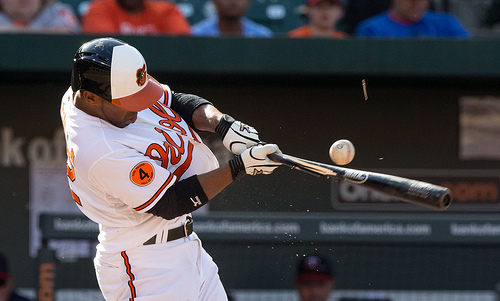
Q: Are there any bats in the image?
A: Yes, there is a bat.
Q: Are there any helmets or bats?
A: Yes, there is a bat.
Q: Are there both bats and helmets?
A: Yes, there are both a bat and a helmet.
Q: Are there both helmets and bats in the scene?
A: Yes, there are both a bat and a helmet.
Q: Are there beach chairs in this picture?
A: No, there are no beach chairs.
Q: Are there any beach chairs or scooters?
A: No, there are no beach chairs or scooters.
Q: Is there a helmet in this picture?
A: Yes, there is a helmet.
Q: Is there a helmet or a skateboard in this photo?
A: Yes, there is a helmet.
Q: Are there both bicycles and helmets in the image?
A: No, there is a helmet but no bicycles.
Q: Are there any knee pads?
A: No, there are no knee pads.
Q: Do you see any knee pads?
A: No, there are no knee pads.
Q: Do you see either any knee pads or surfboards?
A: No, there are no knee pads or surfboards.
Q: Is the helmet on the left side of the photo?
A: Yes, the helmet is on the left of the image.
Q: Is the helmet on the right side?
A: No, the helmet is on the left of the image.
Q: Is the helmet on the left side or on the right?
A: The helmet is on the left of the image.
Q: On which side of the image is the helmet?
A: The helmet is on the left of the image.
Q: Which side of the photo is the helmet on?
A: The helmet is on the left of the image.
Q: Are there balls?
A: Yes, there is a ball.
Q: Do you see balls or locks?
A: Yes, there is a ball.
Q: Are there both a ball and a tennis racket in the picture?
A: No, there is a ball but no rackets.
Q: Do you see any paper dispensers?
A: No, there are no paper dispensers.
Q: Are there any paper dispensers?
A: No, there are no paper dispensers.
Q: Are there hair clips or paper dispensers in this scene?
A: No, there are no paper dispensers or hair clips.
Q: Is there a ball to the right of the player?
A: Yes, there is a ball to the right of the player.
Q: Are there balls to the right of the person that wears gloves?
A: Yes, there is a ball to the right of the player.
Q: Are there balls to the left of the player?
A: No, the ball is to the right of the player.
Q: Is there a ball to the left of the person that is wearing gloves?
A: No, the ball is to the right of the player.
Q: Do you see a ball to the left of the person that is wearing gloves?
A: No, the ball is to the right of the player.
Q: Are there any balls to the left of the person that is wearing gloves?
A: No, the ball is to the right of the player.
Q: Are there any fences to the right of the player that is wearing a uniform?
A: No, there is a ball to the right of the player.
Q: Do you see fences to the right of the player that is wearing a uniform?
A: No, there is a ball to the right of the player.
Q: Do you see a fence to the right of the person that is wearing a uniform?
A: No, there is a ball to the right of the player.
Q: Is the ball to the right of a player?
A: Yes, the ball is to the right of a player.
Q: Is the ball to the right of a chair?
A: No, the ball is to the right of a player.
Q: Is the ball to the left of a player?
A: No, the ball is to the right of a player.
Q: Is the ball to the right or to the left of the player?
A: The ball is to the right of the player.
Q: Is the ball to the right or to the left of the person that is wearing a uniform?
A: The ball is to the right of the player.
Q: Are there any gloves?
A: Yes, there are gloves.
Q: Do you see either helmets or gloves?
A: Yes, there are gloves.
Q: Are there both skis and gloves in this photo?
A: No, there are gloves but no skis.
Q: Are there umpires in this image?
A: No, there are no umpires.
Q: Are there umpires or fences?
A: No, there are no umpires or fences.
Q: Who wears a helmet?
A: The player wears a helmet.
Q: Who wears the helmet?
A: The player wears a helmet.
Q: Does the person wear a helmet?
A: Yes, the player wears a helmet.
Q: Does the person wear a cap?
A: No, the player wears a helmet.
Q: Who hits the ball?
A: The player hits the ball.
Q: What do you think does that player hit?
A: The player hits the ball.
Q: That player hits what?
A: The player hits the ball.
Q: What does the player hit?
A: The player hits the ball.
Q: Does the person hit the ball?
A: Yes, the player hits the ball.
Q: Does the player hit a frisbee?
A: No, the player hits the ball.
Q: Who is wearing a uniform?
A: The player is wearing a uniform.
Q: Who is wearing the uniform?
A: The player is wearing a uniform.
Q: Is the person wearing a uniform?
A: Yes, the player is wearing a uniform.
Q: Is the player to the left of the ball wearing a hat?
A: No, the player is wearing a uniform.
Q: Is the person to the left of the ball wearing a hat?
A: No, the player is wearing a uniform.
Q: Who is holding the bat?
A: The player is holding the bat.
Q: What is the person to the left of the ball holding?
A: The player is holding the bat.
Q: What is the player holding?
A: The player is holding the bat.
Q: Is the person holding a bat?
A: Yes, the player is holding a bat.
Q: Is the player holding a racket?
A: No, the player is holding a bat.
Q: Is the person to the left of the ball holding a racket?
A: No, the player is holding a bat.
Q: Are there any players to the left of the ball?
A: Yes, there is a player to the left of the ball.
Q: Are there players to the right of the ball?
A: No, the player is to the left of the ball.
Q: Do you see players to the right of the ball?
A: No, the player is to the left of the ball.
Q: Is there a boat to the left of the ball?
A: No, there is a player to the left of the ball.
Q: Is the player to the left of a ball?
A: Yes, the player is to the left of a ball.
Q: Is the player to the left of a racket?
A: No, the player is to the left of a ball.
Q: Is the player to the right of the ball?
A: No, the player is to the left of the ball.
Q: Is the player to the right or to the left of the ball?
A: The player is to the left of the ball.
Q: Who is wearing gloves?
A: The player is wearing gloves.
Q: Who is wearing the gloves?
A: The player is wearing gloves.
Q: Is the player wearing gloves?
A: Yes, the player is wearing gloves.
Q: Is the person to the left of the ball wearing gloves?
A: Yes, the player is wearing gloves.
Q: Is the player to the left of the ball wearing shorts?
A: No, the player is wearing gloves.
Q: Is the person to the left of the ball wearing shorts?
A: No, the player is wearing gloves.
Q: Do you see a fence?
A: No, there are no fences.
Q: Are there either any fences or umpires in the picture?
A: No, there are no fences or umpires.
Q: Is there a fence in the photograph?
A: No, there are no fences.